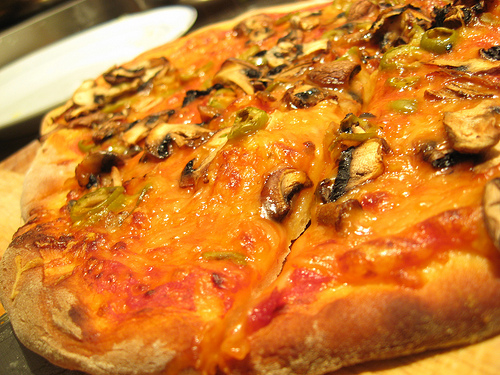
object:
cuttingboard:
[336, 335, 500, 374]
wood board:
[335, 332, 500, 375]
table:
[327, 330, 499, 373]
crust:
[0, 0, 499, 375]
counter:
[0, 0, 225, 68]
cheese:
[44, 0, 485, 374]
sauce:
[244, 265, 335, 337]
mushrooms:
[313, 137, 391, 204]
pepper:
[420, 27, 458, 54]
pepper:
[70, 183, 153, 227]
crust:
[116, 313, 355, 375]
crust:
[11, 266, 210, 375]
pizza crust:
[0, 94, 498, 372]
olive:
[419, 27, 458, 54]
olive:
[384, 76, 420, 89]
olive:
[227, 107, 268, 139]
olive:
[70, 186, 125, 225]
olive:
[78, 138, 100, 152]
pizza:
[0, 0, 500, 372]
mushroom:
[260, 168, 314, 222]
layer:
[0, 2, 499, 375]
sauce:
[75, 255, 200, 322]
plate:
[1, 4, 198, 130]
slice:
[0, 98, 359, 375]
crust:
[246, 220, 467, 357]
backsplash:
[0, 0, 141, 72]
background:
[0, 0, 313, 165]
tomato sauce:
[337, 207, 500, 290]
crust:
[5, 207, 59, 257]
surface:
[328, 333, 500, 374]